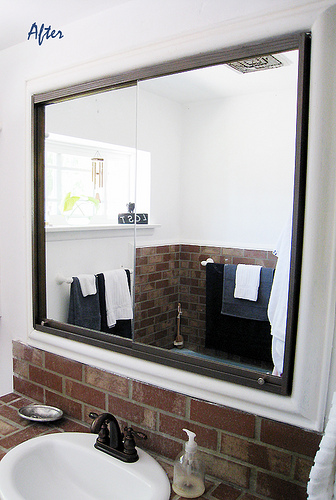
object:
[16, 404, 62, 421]
soap dish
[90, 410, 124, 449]
faucet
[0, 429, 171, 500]
sink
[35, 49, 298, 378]
mirror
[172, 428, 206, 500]
soap bottle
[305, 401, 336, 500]
towels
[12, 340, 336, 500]
wall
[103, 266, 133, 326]
towels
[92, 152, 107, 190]
chime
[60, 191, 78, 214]
plant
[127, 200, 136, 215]
statue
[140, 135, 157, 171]
corner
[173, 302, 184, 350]
brush